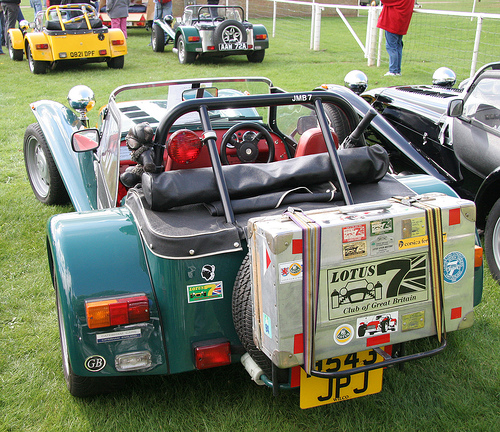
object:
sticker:
[327, 252, 428, 321]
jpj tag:
[299, 348, 383, 409]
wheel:
[481, 192, 499, 285]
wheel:
[178, 35, 196, 64]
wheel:
[151, 25, 164, 52]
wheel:
[28, 45, 46, 74]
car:
[309, 59, 500, 286]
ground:
[0, 0, 500, 432]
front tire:
[23, 123, 69, 205]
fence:
[223, 0, 500, 84]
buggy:
[151, 5, 269, 65]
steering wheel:
[220, 122, 275, 165]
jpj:
[318, 371, 369, 401]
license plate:
[70, 51, 95, 57]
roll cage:
[121, 122, 417, 259]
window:
[97, 110, 117, 209]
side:
[25, 84, 167, 400]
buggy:
[7, 5, 127, 76]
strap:
[283, 206, 322, 377]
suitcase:
[247, 192, 476, 369]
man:
[376, 0, 410, 79]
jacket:
[377, 0, 414, 34]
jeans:
[386, 29, 402, 73]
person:
[106, 0, 128, 39]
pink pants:
[112, 16, 127, 39]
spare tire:
[231, 251, 284, 379]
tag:
[433, 67, 457, 87]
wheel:
[24, 123, 69, 207]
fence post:
[470, 18, 480, 75]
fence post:
[364, 0, 375, 69]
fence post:
[310, 5, 315, 50]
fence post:
[272, 2, 276, 37]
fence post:
[246, 0, 248, 21]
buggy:
[23, 75, 483, 409]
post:
[273, 0, 275, 37]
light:
[86, 296, 150, 329]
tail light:
[195, 343, 231, 370]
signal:
[187, 281, 223, 304]